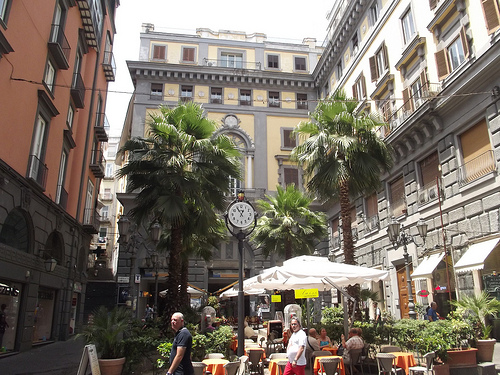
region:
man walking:
[158, 308, 210, 374]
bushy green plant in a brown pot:
[76, 296, 143, 372]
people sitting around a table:
[307, 312, 368, 365]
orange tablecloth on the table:
[382, 339, 414, 374]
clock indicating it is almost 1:
[223, 200, 262, 232]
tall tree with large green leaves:
[108, 91, 229, 325]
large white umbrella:
[212, 227, 403, 314]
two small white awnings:
[401, 244, 498, 282]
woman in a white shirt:
[259, 307, 311, 372]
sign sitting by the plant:
[64, 339, 119, 374]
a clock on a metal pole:
[224, 173, 265, 344]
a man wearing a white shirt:
[281, 308, 312, 356]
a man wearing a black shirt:
[166, 302, 196, 372]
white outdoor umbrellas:
[220, 240, 383, 302]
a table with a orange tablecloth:
[366, 336, 441, 373]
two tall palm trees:
[131, 89, 231, 310]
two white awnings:
[408, 232, 494, 298]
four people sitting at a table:
[295, 321, 369, 361]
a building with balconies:
[95, 126, 128, 296]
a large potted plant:
[83, 310, 136, 372]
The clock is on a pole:
[217, 176, 272, 341]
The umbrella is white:
[205, 243, 405, 305]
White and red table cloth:
[206, 350, 238, 374]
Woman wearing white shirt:
[278, 310, 320, 358]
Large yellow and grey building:
[133, 13, 490, 316]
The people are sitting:
[316, 320, 356, 365]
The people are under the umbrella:
[253, 232, 410, 359]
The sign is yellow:
[293, 286, 338, 313]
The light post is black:
[380, 211, 445, 319]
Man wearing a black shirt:
[154, 293, 196, 368]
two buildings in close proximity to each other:
[6, 0, 497, 371]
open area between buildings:
[16, 95, 463, 372]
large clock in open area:
[221, 180, 261, 355]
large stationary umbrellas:
[217, 237, 388, 357]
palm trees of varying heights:
[125, 67, 379, 327]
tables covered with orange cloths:
[186, 343, 419, 374]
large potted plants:
[365, 290, 497, 371]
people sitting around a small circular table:
[299, 311, 376, 368]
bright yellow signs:
[262, 285, 328, 303]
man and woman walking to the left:
[146, 310, 316, 372]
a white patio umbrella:
[223, 256, 385, 291]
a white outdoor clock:
[220, 190, 258, 352]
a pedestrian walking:
[161, 308, 189, 371]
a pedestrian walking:
[277, 315, 303, 372]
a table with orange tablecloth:
[196, 355, 232, 371]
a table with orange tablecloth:
[267, 355, 297, 370]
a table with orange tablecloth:
[311, 355, 343, 371]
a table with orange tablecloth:
[380, 346, 415, 371]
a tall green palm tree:
[117, 105, 228, 301]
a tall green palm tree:
[300, 101, 391, 289]